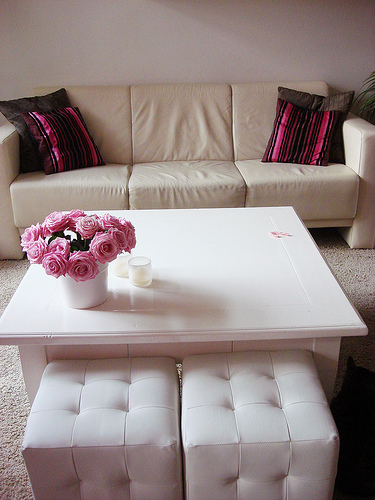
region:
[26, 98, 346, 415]
Beige color scheme living room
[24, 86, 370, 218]
Three cushioned cloth couch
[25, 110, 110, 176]
Throw pillow velvet stripes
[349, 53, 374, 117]
Green plant end table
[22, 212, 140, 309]
Pink flowers white vase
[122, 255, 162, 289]
Clear votive candle holder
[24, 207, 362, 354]
White square coffee table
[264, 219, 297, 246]
Tiny pink ribbon left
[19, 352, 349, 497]
Two cloth covered ottomans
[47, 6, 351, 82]
Plain tan wall nothing there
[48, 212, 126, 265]
the flowers are pink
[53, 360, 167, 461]
the sofa is white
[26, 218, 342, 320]
the table is white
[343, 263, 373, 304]
the carpet is white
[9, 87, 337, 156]
there are four pillows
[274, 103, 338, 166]
the pillow has stripes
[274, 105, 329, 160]
the pillow is orange and black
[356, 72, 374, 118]
the plants is beside the soffa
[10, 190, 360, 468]
the photo was taken indoors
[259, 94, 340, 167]
Black and pink striped pillows.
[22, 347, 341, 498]
Two white cubes with fabric on them.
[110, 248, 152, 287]
Two candle holders on coffee table.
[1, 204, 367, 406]
White coffee table with flowers on it.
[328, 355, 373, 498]
Black cat sitting near coffee table.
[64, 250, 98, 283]
Pink roses on a coffee table.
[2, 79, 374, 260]
Light colored couch with pillows on it.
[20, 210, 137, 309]
White container full of flowers on a coffee table.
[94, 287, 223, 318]
Shadow of vase with flowers on the coffee table.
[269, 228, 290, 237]
Rose petals on a table.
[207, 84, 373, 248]
Two pillows on a couch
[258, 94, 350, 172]
A brown and pink striped pillow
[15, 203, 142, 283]
Pink roses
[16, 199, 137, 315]
A vase of pink roses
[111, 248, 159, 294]
Two candle holders sitting on a table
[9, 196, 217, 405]
A vase of pink roses sitting on a coffee table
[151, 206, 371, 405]
A coffee table sitting in front of a couch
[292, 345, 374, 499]
A black cat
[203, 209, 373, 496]
A black cat sitting by a coffee table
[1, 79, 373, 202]
Four pillows on a couch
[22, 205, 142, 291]
bouquet of pink flowers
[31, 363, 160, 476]
white tufted ottoman seat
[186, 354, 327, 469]
white tufted ottoman seat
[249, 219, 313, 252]
petals on the table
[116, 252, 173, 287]
round candle holder on table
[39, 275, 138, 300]
white ceramic vase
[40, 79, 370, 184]
cream leather 3 seat couch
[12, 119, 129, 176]
pink and black striped pillow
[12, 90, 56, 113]
brown checkered couch table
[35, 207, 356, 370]
white glossy coffee table